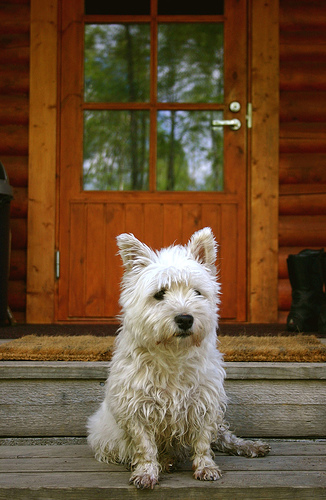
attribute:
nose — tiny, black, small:
[172, 313, 194, 331]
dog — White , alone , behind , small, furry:
[87, 224, 272, 489]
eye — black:
[153, 287, 166, 301]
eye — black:
[192, 286, 203, 295]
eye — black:
[191, 287, 201, 297]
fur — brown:
[155, 333, 204, 348]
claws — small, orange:
[129, 479, 154, 490]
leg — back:
[210, 426, 272, 457]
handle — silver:
[209, 117, 241, 130]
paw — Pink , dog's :
[133, 475, 157, 489]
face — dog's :
[109, 224, 229, 349]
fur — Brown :
[121, 361, 182, 410]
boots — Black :
[281, 250, 315, 333]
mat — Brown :
[6, 329, 315, 359]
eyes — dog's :
[150, 288, 167, 301]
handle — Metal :
[208, 114, 244, 133]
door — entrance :
[41, 9, 282, 330]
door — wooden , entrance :
[48, 13, 268, 343]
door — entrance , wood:
[51, 10, 259, 329]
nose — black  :
[173, 310, 199, 339]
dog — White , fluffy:
[74, 218, 280, 487]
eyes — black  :
[150, 283, 206, 302]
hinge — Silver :
[50, 245, 64, 284]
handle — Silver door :
[210, 99, 253, 136]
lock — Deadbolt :
[211, 100, 245, 132]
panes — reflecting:
[86, 23, 225, 190]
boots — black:
[281, 244, 315, 329]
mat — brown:
[2, 331, 311, 361]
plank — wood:
[280, 183, 325, 210]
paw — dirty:
[125, 472, 160, 492]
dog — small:
[98, 229, 239, 482]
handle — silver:
[204, 117, 244, 131]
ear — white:
[112, 226, 154, 262]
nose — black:
[172, 310, 195, 331]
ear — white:
[185, 223, 224, 273]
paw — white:
[126, 464, 161, 491]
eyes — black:
[151, 280, 207, 301]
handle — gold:
[208, 116, 243, 131]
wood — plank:
[274, 210, 324, 243]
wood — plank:
[277, 149, 324, 186]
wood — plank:
[277, 120, 325, 153]